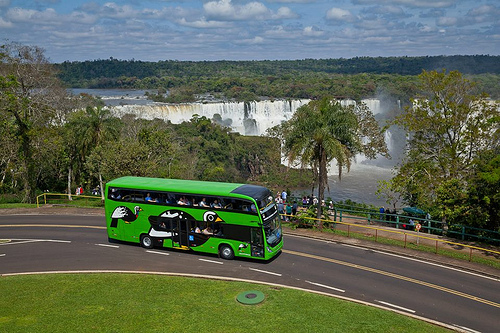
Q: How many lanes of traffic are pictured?
A: Three.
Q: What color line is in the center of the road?
A: Yellow.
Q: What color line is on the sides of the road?
A: White.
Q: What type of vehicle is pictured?
A: Bus.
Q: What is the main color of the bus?
A: Green.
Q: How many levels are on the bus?
A: Two.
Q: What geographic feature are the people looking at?
A: Waterfall.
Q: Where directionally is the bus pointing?
A: Right.